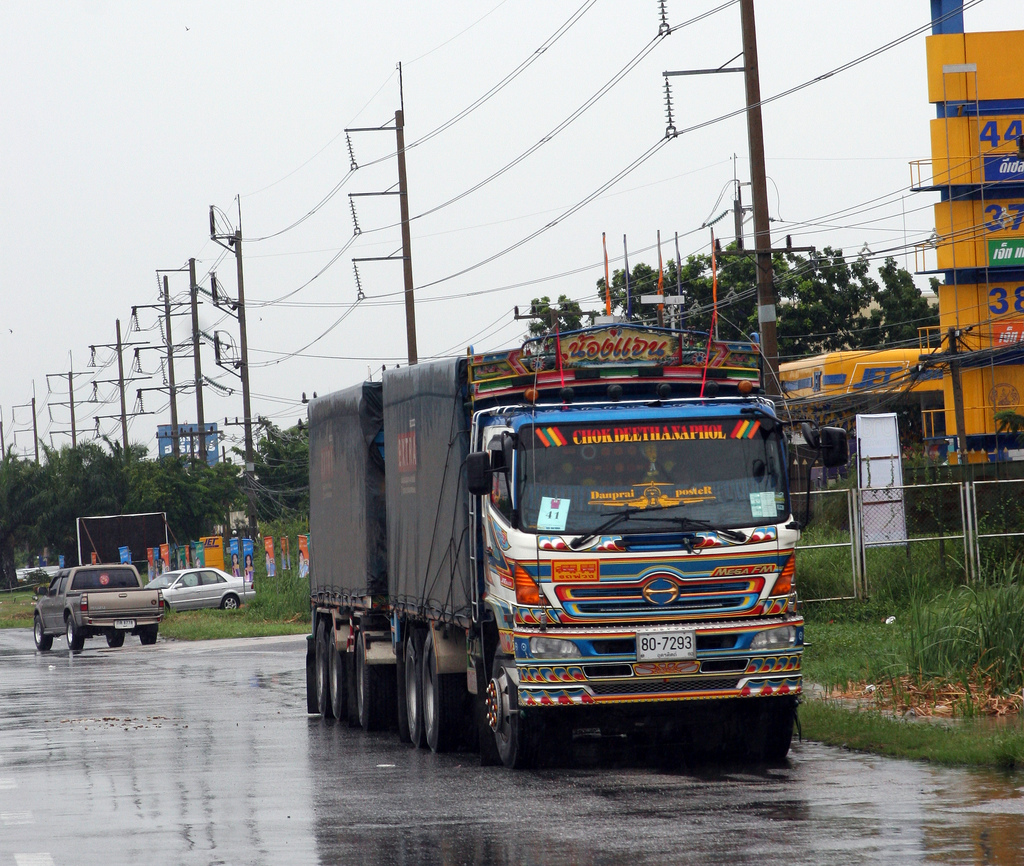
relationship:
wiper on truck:
[564, 482, 698, 556] [294, 318, 809, 772]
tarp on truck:
[376, 348, 480, 636] [294, 318, 809, 772]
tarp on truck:
[296, 372, 379, 623] [294, 318, 809, 772]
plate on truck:
[108, 611, 139, 638] [20, 557, 178, 659]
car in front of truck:
[153, 555, 264, 618] [22, 551, 170, 662]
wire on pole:
[257, 132, 392, 245] [384, 112, 424, 365]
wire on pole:
[242, 212, 402, 318] [384, 112, 424, 365]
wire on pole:
[246, 281, 400, 368] [384, 112, 424, 365]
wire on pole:
[239, 132, 404, 248] [384, 112, 424, 365]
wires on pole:
[652, 0, 750, 266] [734, 0, 786, 387]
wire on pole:
[239, 132, 404, 248] [222, 197, 261, 528]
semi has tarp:
[281, 346, 811, 774] [307, 380, 387, 605]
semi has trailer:
[281, 346, 811, 774] [380, 350, 497, 638]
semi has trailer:
[281, 346, 811, 774] [298, 376, 383, 616]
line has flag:
[115, 527, 260, 571] [257, 529, 281, 558]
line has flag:
[115, 527, 260, 571] [186, 529, 213, 566]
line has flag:
[115, 527, 260, 571] [147, 533, 169, 572]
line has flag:
[115, 527, 260, 571] [108, 540, 137, 566]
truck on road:
[20, 568, 183, 657] [6, 631, 1022, 861]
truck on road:
[32, 564, 157, 650] [6, 631, 1022, 861]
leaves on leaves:
[528, 246, 949, 369] [528, 246, 949, 369]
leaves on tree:
[531, 255, 936, 370] [538, 255, 940, 511]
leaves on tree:
[125, 397, 270, 560] [106, 416, 269, 561]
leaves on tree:
[132, 430, 243, 549] [140, 404, 251, 552]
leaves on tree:
[110, 438, 225, 553] [84, 434, 244, 564]